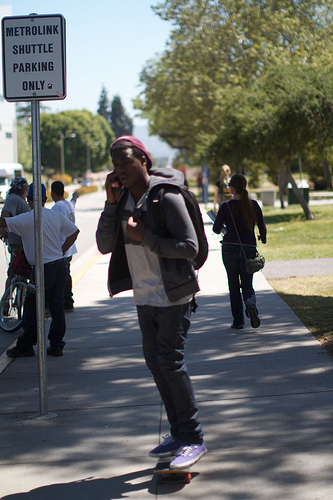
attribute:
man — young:
[95, 135, 211, 461]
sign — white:
[0, 16, 69, 108]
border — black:
[7, 14, 68, 102]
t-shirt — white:
[2, 204, 79, 263]